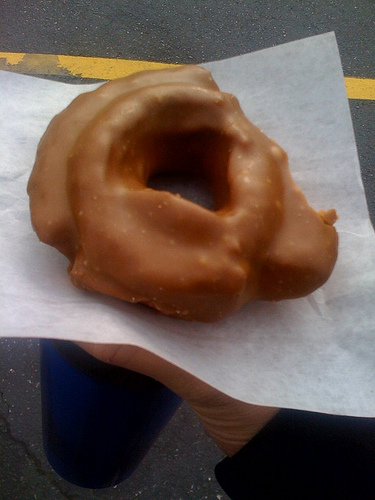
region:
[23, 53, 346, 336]
brown glazed donut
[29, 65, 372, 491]
hand holding a cup and a donut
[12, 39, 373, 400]
donut on white paper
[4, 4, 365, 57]
asphalt road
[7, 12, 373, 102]
bright yellow line on an asphalt road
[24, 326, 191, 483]
blue cup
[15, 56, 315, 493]
donut balanced on top of a blue cup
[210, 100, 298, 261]
small bubbles in donut glaze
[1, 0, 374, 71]
small pieces of rock in asphalt road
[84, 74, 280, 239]
hole in the center of a donut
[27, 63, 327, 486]
man holding doughnut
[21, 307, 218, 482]
man holding cup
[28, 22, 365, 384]
man holding doughnut on tissue paper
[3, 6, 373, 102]
road pavement with yellow divider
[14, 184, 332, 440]
tissue paper for handling doughnut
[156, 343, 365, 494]
sleeve covering a hand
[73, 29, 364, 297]
partially eaten doughnut with crumb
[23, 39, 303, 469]
man holding doughnut, tissue paper, and cup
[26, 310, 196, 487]
cup for holding beverage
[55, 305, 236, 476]
thumb resting on cup and supporting doughnut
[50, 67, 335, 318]
brown food on person's hand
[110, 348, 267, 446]
hand holding food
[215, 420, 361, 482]
long sleeve of clothing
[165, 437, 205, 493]
black street below man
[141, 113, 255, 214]
hole in middle of donut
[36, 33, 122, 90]
yellow line on street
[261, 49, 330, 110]
white paper around donut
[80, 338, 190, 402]
thumb of person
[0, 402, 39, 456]
crack in the street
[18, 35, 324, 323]
doughnut on white paper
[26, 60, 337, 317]
Brown frosted donut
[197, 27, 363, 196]
White parchment paper under donuts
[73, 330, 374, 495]
Person's hand under paper and donut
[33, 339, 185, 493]
Blue travel mug in person's hand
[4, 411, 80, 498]
large crack in asphalt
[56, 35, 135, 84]
Yellow line on asphalt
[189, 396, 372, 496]
Black jacket woman is wearing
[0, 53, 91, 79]
Faded patch of yellow line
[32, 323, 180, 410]
Black rim around coffee mug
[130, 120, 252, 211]
irregular hole in donut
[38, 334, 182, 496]
plastic cup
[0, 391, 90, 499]
crack in the asphalt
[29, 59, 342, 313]
glaze covered donut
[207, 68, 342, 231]
bite taken out of glaze covered donut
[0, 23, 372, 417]
parchment paper holding a donut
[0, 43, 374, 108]
yellow painted line on a roadway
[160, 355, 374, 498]
person's arm in a black fleece jacket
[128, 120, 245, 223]
hole in the center of the donut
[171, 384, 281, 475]
wrinkles in the skin on a person's hand